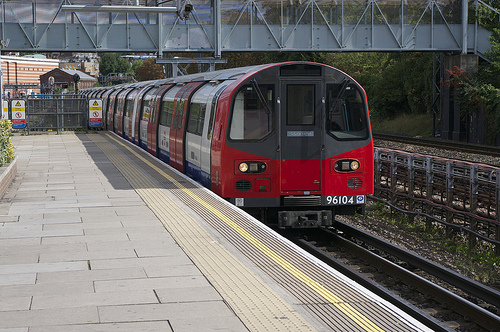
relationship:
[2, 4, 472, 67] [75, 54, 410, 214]
metal structure above train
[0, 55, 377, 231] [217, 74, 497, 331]
train on tracks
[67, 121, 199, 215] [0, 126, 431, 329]
shadow on ground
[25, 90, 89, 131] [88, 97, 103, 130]
metal fence beside sign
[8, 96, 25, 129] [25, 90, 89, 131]
sign beside metal fence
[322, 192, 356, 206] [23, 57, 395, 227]
numbers on train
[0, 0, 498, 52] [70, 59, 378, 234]
walkway over train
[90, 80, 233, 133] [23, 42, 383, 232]
reflection on train